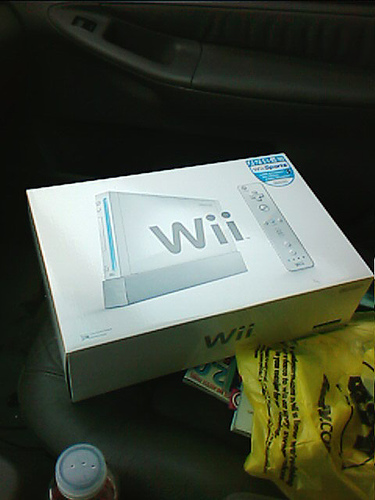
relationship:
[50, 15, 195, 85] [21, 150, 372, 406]
door handle above box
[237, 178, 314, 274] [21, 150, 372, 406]
remote on box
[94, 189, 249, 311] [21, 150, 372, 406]
console on box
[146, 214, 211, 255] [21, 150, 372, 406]
letter on a box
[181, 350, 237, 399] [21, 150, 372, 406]
magazine beneath box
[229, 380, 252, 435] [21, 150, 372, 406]
magazine beneath box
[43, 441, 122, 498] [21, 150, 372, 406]
drink below box